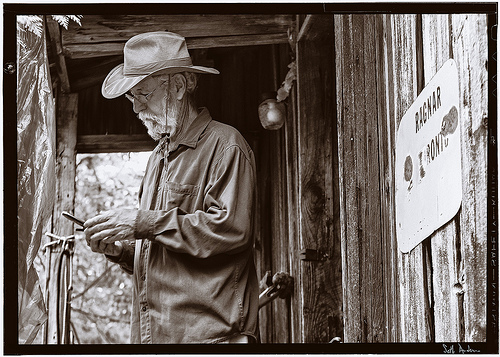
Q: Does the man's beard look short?
A: Yes, the beard is short.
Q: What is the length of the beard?
A: The beard is short.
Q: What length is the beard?
A: The beard is short.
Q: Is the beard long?
A: No, the beard is short.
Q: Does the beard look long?
A: No, the beard is short.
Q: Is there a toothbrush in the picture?
A: No, there are no toothbrushes.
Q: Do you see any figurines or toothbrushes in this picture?
A: No, there are no toothbrushes or figurines.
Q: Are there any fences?
A: No, there are no fences.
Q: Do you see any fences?
A: No, there are no fences.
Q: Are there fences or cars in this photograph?
A: No, there are no fences or cars.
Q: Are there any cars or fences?
A: No, there are no fences or cars.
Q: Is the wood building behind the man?
A: Yes, the building is behind the man.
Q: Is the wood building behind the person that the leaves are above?
A: Yes, the building is behind the man.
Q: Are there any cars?
A: No, there are no cars.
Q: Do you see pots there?
A: No, there are no pots.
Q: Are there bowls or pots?
A: No, there are no pots or bowls.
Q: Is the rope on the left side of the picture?
A: Yes, the rope is on the left of the image.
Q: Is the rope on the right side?
A: No, the rope is on the left of the image.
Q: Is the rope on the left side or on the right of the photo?
A: The rope is on the left of the image.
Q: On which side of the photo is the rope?
A: The rope is on the left of the image.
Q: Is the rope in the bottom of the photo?
A: Yes, the rope is in the bottom of the image.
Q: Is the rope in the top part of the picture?
A: No, the rope is in the bottom of the image.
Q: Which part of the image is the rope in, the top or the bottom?
A: The rope is in the bottom of the image.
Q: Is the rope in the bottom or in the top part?
A: The rope is in the bottom of the image.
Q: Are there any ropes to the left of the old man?
A: Yes, there is a rope to the left of the man.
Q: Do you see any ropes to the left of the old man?
A: Yes, there is a rope to the left of the man.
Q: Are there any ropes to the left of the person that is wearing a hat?
A: Yes, there is a rope to the left of the man.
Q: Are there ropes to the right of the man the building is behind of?
A: No, the rope is to the left of the man.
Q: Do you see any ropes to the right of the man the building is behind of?
A: No, the rope is to the left of the man.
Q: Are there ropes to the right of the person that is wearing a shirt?
A: No, the rope is to the left of the man.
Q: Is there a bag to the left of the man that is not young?
A: No, there is a rope to the left of the man.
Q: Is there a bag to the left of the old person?
A: No, there is a rope to the left of the man.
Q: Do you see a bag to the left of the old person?
A: No, there is a rope to the left of the man.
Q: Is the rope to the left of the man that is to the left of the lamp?
A: Yes, the rope is to the left of the man.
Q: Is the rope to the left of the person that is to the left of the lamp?
A: Yes, the rope is to the left of the man.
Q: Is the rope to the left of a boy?
A: No, the rope is to the left of the man.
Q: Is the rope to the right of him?
A: No, the rope is to the left of a man.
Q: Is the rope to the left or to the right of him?
A: The rope is to the left of the man.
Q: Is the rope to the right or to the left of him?
A: The rope is to the left of the man.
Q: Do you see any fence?
A: No, there are no fences.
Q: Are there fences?
A: No, there are no fences.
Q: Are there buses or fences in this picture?
A: No, there are no fences or buses.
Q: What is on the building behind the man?
A: The sign is on the building.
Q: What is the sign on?
A: The sign is on the building.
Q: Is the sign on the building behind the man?
A: Yes, the sign is on the building.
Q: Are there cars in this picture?
A: No, there are no cars.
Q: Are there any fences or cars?
A: No, there are no cars or fences.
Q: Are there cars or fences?
A: No, there are no cars or fences.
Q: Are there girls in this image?
A: No, there are no girls.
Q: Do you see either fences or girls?
A: No, there are no girls or fences.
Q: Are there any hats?
A: Yes, there is a hat.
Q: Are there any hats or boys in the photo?
A: Yes, there is a hat.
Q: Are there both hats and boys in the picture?
A: No, there is a hat but no boys.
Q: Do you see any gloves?
A: No, there are no gloves.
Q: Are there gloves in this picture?
A: No, there are no gloves.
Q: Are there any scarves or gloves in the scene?
A: No, there are no gloves or scarves.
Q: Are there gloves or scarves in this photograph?
A: No, there are no gloves or scarves.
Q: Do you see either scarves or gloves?
A: No, there are no gloves or scarves.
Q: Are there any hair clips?
A: No, there are no hair clips.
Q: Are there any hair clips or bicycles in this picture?
A: No, there are no hair clips or bicycles.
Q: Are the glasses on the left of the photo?
A: Yes, the glasses are on the left of the image.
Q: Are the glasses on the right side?
A: No, the glasses are on the left of the image.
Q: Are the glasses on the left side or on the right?
A: The glasses are on the left of the image.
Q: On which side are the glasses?
A: The glasses are on the left of the image.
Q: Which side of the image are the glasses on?
A: The glasses are on the left of the image.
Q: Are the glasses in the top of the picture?
A: Yes, the glasses are in the top of the image.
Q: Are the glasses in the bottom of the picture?
A: No, the glasses are in the top of the image.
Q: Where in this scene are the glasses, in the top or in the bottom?
A: The glasses are in the top of the image.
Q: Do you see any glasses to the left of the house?
A: Yes, there are glasses to the left of the house.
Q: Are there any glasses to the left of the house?
A: Yes, there are glasses to the left of the house.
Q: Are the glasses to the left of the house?
A: Yes, the glasses are to the left of the house.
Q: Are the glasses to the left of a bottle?
A: No, the glasses are to the left of the house.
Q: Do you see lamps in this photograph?
A: Yes, there is a lamp.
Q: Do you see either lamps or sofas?
A: Yes, there is a lamp.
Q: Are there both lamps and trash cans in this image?
A: No, there is a lamp but no trash cans.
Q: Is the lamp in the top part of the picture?
A: Yes, the lamp is in the top of the image.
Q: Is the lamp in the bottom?
A: No, the lamp is in the top of the image.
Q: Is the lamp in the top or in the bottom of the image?
A: The lamp is in the top of the image.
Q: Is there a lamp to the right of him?
A: Yes, there is a lamp to the right of the man.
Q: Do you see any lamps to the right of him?
A: Yes, there is a lamp to the right of the man.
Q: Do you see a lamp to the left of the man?
A: No, the lamp is to the right of the man.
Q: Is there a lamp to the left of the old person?
A: No, the lamp is to the right of the man.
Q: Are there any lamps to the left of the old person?
A: No, the lamp is to the right of the man.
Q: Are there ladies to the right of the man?
A: No, there is a lamp to the right of the man.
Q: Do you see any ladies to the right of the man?
A: No, there is a lamp to the right of the man.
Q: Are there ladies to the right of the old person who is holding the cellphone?
A: No, there is a lamp to the right of the man.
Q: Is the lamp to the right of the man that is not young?
A: Yes, the lamp is to the right of the man.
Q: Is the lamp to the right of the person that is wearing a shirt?
A: Yes, the lamp is to the right of the man.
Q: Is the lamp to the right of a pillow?
A: No, the lamp is to the right of the man.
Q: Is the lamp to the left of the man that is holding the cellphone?
A: No, the lamp is to the right of the man.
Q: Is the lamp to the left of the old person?
A: No, the lamp is to the right of the man.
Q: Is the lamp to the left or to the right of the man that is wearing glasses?
A: The lamp is to the right of the man.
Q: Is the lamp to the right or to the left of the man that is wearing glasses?
A: The lamp is to the right of the man.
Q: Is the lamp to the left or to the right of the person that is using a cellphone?
A: The lamp is to the right of the man.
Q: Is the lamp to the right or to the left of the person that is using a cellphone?
A: The lamp is to the right of the man.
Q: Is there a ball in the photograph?
A: No, there are no balls.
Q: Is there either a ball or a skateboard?
A: No, there are no balls or skateboards.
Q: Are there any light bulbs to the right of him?
A: Yes, there is a light bulb to the right of the man.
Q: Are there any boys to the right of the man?
A: No, there is a light bulb to the right of the man.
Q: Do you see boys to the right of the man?
A: No, there is a light bulb to the right of the man.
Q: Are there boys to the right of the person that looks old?
A: No, there is a light bulb to the right of the man.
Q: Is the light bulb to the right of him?
A: Yes, the light bulb is to the right of a man.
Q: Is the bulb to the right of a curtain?
A: No, the bulb is to the right of a man.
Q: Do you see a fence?
A: No, there are no fences.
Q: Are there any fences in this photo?
A: No, there are no fences.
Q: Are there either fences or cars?
A: No, there are no fences or cars.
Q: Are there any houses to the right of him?
A: Yes, there is a house to the right of the man.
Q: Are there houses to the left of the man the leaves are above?
A: No, the house is to the right of the man.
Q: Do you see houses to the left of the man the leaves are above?
A: No, the house is to the right of the man.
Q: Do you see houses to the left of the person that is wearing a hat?
A: No, the house is to the right of the man.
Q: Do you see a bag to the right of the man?
A: No, there is a house to the right of the man.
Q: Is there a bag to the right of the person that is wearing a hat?
A: No, there is a house to the right of the man.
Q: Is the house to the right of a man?
A: Yes, the house is to the right of a man.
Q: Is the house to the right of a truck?
A: No, the house is to the right of a man.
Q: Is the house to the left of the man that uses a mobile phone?
A: No, the house is to the right of the man.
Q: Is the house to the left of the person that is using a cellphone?
A: No, the house is to the right of the man.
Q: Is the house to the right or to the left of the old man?
A: The house is to the right of the man.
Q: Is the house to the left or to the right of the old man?
A: The house is to the right of the man.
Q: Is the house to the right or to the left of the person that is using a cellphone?
A: The house is to the right of the man.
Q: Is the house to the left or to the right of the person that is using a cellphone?
A: The house is to the right of the man.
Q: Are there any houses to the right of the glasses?
A: Yes, there is a house to the right of the glasses.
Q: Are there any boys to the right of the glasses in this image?
A: No, there is a house to the right of the glasses.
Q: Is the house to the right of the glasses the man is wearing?
A: Yes, the house is to the right of the glasses.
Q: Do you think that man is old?
A: Yes, the man is old.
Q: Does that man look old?
A: Yes, the man is old.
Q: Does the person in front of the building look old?
A: Yes, the man is old.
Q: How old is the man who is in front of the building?
A: The man is old.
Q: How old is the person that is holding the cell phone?
A: The man is old.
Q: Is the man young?
A: No, the man is old.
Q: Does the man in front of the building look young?
A: No, the man is old.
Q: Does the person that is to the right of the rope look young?
A: No, the man is old.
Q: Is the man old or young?
A: The man is old.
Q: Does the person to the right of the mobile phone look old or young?
A: The man is old.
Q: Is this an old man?
A: Yes, this is an old man.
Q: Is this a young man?
A: No, this is an old man.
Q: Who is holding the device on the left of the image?
A: The man is holding the cell phone.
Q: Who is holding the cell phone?
A: The man is holding the cell phone.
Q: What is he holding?
A: The man is holding the cellphone.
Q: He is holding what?
A: The man is holding the cellphone.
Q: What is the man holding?
A: The man is holding the cellphone.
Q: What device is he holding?
A: The man is holding the mobile phone.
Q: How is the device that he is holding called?
A: The device is a cell phone.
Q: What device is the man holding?
A: The man is holding the mobile phone.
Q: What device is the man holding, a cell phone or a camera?
A: The man is holding a cell phone.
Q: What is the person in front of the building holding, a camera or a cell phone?
A: The man is holding a cell phone.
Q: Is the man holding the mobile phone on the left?
A: Yes, the man is holding the mobile phone.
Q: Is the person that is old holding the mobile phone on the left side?
A: Yes, the man is holding the mobile phone.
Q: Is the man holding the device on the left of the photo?
A: Yes, the man is holding the mobile phone.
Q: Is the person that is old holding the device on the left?
A: Yes, the man is holding the mobile phone.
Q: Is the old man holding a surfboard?
A: No, the man is holding the mobile phone.